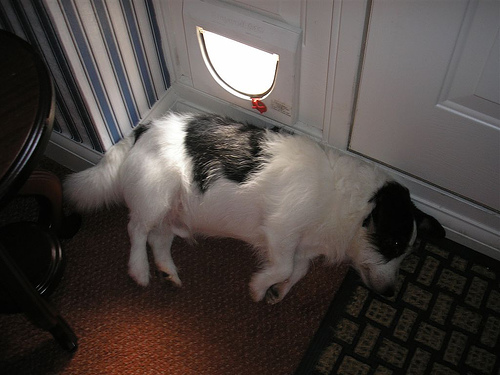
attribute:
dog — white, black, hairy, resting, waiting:
[60, 111, 445, 303]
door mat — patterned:
[297, 211, 499, 375]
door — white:
[345, 1, 499, 212]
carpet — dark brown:
[0, 188, 357, 375]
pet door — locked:
[172, 3, 303, 128]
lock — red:
[251, 100, 267, 114]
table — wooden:
[2, 27, 81, 353]